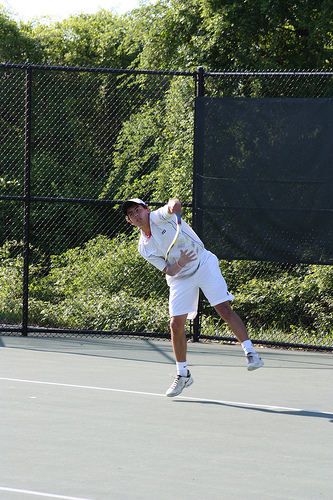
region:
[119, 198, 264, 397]
young man holding a tennis racket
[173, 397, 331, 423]
man's shadow on the tennis court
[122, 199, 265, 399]
man wearing a cap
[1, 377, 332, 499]
white lines on the tennis court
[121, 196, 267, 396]
man wearing white shorts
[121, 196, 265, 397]
young man with both feet in air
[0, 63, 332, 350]
metal fence behind man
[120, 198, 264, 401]
young man wearing sneakers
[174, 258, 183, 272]
wristband in right wrist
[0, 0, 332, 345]
trees behind fence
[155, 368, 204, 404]
right foot on person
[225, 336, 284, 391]
left foot on person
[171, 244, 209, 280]
right hand on person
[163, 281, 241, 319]
person in white shorts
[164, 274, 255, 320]
white shorts on person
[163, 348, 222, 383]
white socks on person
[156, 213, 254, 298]
person holding tennis racket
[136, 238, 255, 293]
person in white shirt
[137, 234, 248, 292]
white shirt on person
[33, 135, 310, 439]
man playing on tennis court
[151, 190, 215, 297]
man holding tennis racket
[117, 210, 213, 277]
man wearing white shirt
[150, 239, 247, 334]
man wearing white shorts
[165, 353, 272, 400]
man wearing white shoes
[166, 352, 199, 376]
man wearing white socks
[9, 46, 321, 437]
black fence behind tennis player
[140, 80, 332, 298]
black fabric hanging on fence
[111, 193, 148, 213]
man wearing baseball hat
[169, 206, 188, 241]
tennis racket has blue handle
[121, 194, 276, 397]
MAN IS OFF THE GROUND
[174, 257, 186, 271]
MAN IS WEARING AN ORANGE BRACELET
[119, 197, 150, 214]
MAN IS WEARING A WHITE HAT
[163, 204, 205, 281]
MAN IS SWINGING A TENNIS RACKET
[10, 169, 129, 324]
CHAIN LINK FENCE SURROUNDS THE TENNIS COURT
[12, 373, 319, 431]
WHITE LINES ARE PAINTED ON THE COURT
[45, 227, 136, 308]
GREEN FOLIAGE IS IN THE BACKGROUND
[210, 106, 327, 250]
A BLACK SCREEN IS ON THE FENCE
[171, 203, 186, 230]
HANDLE OF TENNIS RACKET IS RED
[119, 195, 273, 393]
MAN IS DRESSED IN ALL WHITE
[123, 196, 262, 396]
guy in white playing tennis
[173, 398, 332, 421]
shadow of a tennis player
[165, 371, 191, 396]
white shoe for sports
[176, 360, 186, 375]
white sock for sports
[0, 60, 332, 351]
fence around a tennis field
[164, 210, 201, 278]
blue and yellow tennis racket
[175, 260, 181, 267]
pink bracelet on a guy's wrist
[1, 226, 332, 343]
bushes behind a fence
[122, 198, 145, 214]
white hat on a guy's head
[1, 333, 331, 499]
blue tennis court